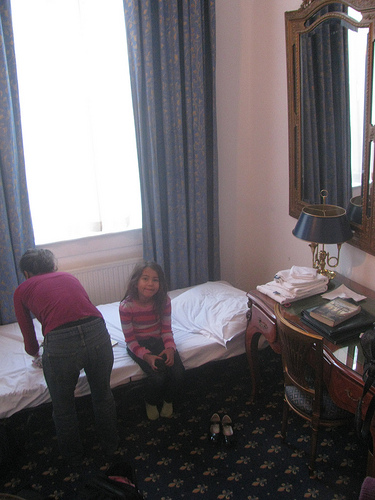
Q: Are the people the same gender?
A: Yes, all the people are female.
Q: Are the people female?
A: Yes, all the people are female.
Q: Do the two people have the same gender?
A: Yes, all the people are female.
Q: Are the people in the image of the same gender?
A: Yes, all the people are female.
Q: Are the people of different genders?
A: No, all the people are female.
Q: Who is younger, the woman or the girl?
A: The girl is younger than the woman.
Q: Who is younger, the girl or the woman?
A: The girl is younger than the woman.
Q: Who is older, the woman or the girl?
A: The woman is older than the girl.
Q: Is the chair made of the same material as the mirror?
A: Yes, both the chair and the mirror are made of wood.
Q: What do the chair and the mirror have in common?
A: The material, both the chair and the mirror are wooden.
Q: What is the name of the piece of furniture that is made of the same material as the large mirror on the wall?
A: The piece of furniture is a chair.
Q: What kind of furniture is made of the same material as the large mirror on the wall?
A: The chair is made of the same material as the mirror.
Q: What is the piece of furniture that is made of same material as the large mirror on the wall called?
A: The piece of furniture is a chair.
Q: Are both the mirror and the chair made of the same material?
A: Yes, both the mirror and the chair are made of wood.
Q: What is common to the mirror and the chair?
A: The material, both the mirror and the chair are wooden.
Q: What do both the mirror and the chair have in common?
A: The material, both the mirror and the chair are wooden.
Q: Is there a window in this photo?
A: Yes, there is a window.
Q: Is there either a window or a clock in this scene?
A: Yes, there is a window.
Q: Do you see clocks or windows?
A: Yes, there is a window.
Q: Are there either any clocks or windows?
A: Yes, there is a window.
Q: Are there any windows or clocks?
A: Yes, there is a window.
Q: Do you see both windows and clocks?
A: No, there is a window but no clocks.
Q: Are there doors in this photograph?
A: No, there are no doors.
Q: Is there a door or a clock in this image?
A: No, there are no doors or clocks.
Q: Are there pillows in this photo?
A: Yes, there is a pillow.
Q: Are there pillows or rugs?
A: Yes, there is a pillow.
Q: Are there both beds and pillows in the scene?
A: Yes, there are both a pillow and a bed.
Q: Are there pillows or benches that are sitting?
A: Yes, the pillow is sitting.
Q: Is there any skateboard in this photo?
A: No, there are no skateboards.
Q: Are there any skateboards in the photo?
A: No, there are no skateboards.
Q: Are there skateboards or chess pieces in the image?
A: No, there are no skateboards or chess pieces.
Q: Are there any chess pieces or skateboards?
A: No, there are no skateboards or chess pieces.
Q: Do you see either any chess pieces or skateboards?
A: No, there are no skateboards or chess pieces.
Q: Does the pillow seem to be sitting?
A: Yes, the pillow is sitting.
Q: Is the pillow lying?
A: No, the pillow is sitting.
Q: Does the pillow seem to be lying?
A: No, the pillow is sitting.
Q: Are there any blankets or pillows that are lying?
A: No, there is a pillow but it is sitting.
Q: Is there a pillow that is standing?
A: No, there is a pillow but it is sitting.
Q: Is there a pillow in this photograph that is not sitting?
A: No, there is a pillow but it is sitting.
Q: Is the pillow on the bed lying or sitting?
A: The pillow is sitting.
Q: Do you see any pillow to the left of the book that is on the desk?
A: Yes, there is a pillow to the left of the book.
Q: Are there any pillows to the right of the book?
A: No, the pillow is to the left of the book.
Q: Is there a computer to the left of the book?
A: No, there is a pillow to the left of the book.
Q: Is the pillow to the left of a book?
A: Yes, the pillow is to the left of a book.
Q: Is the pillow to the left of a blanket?
A: No, the pillow is to the left of a book.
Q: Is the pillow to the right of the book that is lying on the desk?
A: No, the pillow is to the left of the book.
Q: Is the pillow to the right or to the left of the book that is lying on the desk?
A: The pillow is to the left of the book.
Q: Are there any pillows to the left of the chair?
A: Yes, there is a pillow to the left of the chair.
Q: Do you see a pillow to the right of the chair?
A: No, the pillow is to the left of the chair.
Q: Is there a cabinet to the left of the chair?
A: No, there is a pillow to the left of the chair.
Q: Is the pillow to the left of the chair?
A: Yes, the pillow is to the left of the chair.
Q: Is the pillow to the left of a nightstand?
A: No, the pillow is to the left of the chair.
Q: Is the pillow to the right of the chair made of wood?
A: No, the pillow is to the left of the chair.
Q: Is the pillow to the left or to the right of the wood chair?
A: The pillow is to the left of the chair.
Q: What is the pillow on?
A: The pillow is on the bed.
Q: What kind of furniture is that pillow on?
A: The pillow is on the bed.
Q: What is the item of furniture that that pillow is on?
A: The piece of furniture is a bed.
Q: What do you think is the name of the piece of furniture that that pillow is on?
A: The piece of furniture is a bed.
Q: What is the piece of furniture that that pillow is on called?
A: The piece of furniture is a bed.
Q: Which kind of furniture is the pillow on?
A: The pillow is on the bed.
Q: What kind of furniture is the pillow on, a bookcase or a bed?
A: The pillow is on a bed.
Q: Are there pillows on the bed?
A: Yes, there is a pillow on the bed.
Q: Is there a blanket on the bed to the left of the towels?
A: No, there is a pillow on the bed.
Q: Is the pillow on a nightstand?
A: No, the pillow is on the bed.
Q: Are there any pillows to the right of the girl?
A: Yes, there is a pillow to the right of the girl.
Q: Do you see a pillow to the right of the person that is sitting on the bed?
A: Yes, there is a pillow to the right of the girl.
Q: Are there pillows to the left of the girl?
A: No, the pillow is to the right of the girl.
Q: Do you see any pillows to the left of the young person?
A: No, the pillow is to the right of the girl.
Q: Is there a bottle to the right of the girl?
A: No, there is a pillow to the right of the girl.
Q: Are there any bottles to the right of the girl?
A: No, there is a pillow to the right of the girl.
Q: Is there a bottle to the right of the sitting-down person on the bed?
A: No, there is a pillow to the right of the girl.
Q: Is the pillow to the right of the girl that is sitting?
A: Yes, the pillow is to the right of the girl.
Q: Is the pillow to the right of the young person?
A: Yes, the pillow is to the right of the girl.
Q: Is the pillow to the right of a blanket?
A: No, the pillow is to the right of the girl.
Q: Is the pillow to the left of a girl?
A: No, the pillow is to the right of a girl.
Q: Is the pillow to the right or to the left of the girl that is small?
A: The pillow is to the right of the girl.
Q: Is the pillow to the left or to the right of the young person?
A: The pillow is to the right of the girl.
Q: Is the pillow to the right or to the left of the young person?
A: The pillow is to the right of the girl.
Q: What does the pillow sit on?
A: The pillow sits on the bed.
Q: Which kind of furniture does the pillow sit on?
A: The pillow sits on the bed.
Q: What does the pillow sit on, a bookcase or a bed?
A: The pillow sits on a bed.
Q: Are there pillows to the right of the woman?
A: Yes, there is a pillow to the right of the woman.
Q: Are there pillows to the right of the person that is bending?
A: Yes, there is a pillow to the right of the woman.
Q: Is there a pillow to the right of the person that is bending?
A: Yes, there is a pillow to the right of the woman.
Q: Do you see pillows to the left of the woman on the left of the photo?
A: No, the pillow is to the right of the woman.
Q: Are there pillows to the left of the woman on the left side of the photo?
A: No, the pillow is to the right of the woman.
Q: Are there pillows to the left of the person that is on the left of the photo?
A: No, the pillow is to the right of the woman.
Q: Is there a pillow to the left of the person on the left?
A: No, the pillow is to the right of the woman.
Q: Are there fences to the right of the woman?
A: No, there is a pillow to the right of the woman.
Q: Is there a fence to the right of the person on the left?
A: No, there is a pillow to the right of the woman.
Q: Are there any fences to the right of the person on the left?
A: No, there is a pillow to the right of the woman.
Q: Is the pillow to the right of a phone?
A: No, the pillow is to the right of a woman.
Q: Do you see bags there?
A: Yes, there is a bag.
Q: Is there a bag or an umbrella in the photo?
A: Yes, there is a bag.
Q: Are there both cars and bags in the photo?
A: No, there is a bag but no cars.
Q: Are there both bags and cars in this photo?
A: No, there is a bag but no cars.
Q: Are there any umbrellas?
A: No, there are no umbrellas.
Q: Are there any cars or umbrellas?
A: No, there are no umbrellas or cars.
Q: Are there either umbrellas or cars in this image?
A: No, there are no umbrellas or cars.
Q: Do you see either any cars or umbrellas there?
A: No, there are no umbrellas or cars.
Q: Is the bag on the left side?
A: Yes, the bag is on the left of the image.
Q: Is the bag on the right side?
A: No, the bag is on the left of the image.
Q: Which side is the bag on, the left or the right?
A: The bag is on the left of the image.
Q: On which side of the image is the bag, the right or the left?
A: The bag is on the left of the image.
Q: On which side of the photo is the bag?
A: The bag is on the left of the image.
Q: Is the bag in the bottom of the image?
A: Yes, the bag is in the bottom of the image.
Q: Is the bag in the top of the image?
A: No, the bag is in the bottom of the image.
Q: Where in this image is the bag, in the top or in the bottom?
A: The bag is in the bottom of the image.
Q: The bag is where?
A: The bag is on the floor.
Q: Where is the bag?
A: The bag is on the floor.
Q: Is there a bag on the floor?
A: Yes, there is a bag on the floor.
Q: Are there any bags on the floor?
A: Yes, there is a bag on the floor.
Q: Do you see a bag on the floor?
A: Yes, there is a bag on the floor.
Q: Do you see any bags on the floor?
A: Yes, there is a bag on the floor.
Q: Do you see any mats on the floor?
A: No, there is a bag on the floor.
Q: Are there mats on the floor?
A: No, there is a bag on the floor.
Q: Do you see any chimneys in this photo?
A: No, there are no chimneys.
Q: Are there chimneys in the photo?
A: No, there are no chimneys.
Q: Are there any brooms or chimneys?
A: No, there are no chimneys or brooms.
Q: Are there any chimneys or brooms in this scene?
A: No, there are no chimneys or brooms.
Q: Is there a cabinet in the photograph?
A: No, there are no cabinets.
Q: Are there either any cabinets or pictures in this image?
A: No, there are no cabinets or pictures.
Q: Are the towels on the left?
A: No, the towels are on the right of the image.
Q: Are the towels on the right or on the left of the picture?
A: The towels are on the right of the image.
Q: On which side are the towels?
A: The towels are on the right of the image.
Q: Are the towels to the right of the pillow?
A: Yes, the towels are to the right of the pillow.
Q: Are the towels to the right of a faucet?
A: No, the towels are to the right of the pillow.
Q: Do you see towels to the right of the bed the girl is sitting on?
A: Yes, there are towels to the right of the bed.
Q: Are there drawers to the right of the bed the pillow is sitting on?
A: No, there are towels to the right of the bed.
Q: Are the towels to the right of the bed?
A: Yes, the towels are to the right of the bed.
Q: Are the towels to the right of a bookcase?
A: No, the towels are to the right of the bed.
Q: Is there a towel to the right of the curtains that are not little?
A: Yes, there are towels to the right of the curtains.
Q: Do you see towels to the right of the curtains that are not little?
A: Yes, there are towels to the right of the curtains.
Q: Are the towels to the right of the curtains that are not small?
A: Yes, the towels are to the right of the curtains.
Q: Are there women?
A: Yes, there is a woman.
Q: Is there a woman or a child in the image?
A: Yes, there is a woman.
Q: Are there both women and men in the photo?
A: No, there is a woman but no men.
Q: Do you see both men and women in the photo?
A: No, there is a woman but no men.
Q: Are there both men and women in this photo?
A: No, there is a woman but no men.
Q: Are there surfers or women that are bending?
A: Yes, the woman is bending.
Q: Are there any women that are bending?
A: Yes, there is a woman that is bending.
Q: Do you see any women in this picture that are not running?
A: Yes, there is a woman that is bending .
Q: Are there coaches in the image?
A: No, there are no coaches.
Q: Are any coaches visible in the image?
A: No, there are no coaches.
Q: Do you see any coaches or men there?
A: No, there are no coaches or men.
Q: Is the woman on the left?
A: Yes, the woman is on the left of the image.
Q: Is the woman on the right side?
A: No, the woman is on the left of the image.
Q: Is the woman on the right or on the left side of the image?
A: The woman is on the left of the image.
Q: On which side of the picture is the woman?
A: The woman is on the left of the image.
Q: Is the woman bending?
A: Yes, the woman is bending.